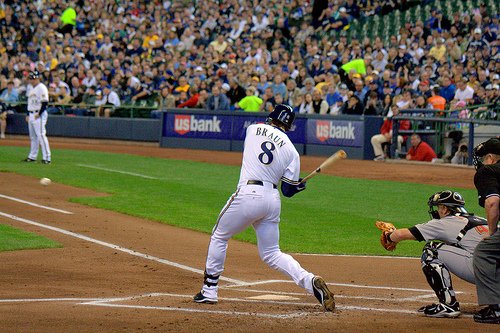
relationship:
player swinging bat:
[194, 103, 334, 311] [298, 151, 346, 187]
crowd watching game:
[0, 1, 499, 124] [0, 116, 497, 320]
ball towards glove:
[39, 175, 53, 189] [374, 221, 398, 251]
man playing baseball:
[194, 103, 334, 311] [0, 116, 497, 320]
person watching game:
[235, 87, 264, 111] [0, 116, 497, 320]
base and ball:
[248, 287, 302, 303] [39, 175, 53, 189]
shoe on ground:
[191, 290, 218, 303] [82, 287, 413, 332]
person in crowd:
[211, 34, 229, 51] [0, 1, 499, 124]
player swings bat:
[194, 103, 334, 311] [298, 151, 346, 187]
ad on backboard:
[164, 115, 231, 138] [161, 109, 233, 150]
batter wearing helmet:
[194, 103, 334, 311] [267, 105, 293, 129]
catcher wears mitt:
[374, 192, 500, 315] [374, 221, 398, 251]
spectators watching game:
[0, 1, 499, 124] [0, 116, 497, 320]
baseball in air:
[39, 175, 53, 189] [30, 161, 68, 205]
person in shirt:
[235, 87, 264, 111] [242, 98, 260, 110]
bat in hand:
[298, 151, 346, 187] [293, 180, 304, 189]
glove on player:
[374, 221, 398, 251] [374, 192, 500, 315]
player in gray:
[374, 192, 500, 315] [418, 217, 495, 282]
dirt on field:
[2, 173, 499, 331] [1, 135, 499, 326]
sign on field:
[164, 115, 231, 138] [1, 135, 499, 326]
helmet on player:
[267, 105, 293, 129] [194, 103, 334, 311]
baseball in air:
[41, 179, 52, 189] [30, 161, 68, 205]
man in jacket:
[407, 135, 437, 163] [407, 142, 434, 158]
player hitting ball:
[194, 103, 334, 311] [39, 175, 53, 189]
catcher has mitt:
[374, 192, 500, 315] [374, 221, 398, 251]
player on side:
[25, 71, 52, 164] [2, 1, 66, 322]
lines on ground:
[81, 289, 330, 321] [82, 287, 413, 332]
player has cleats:
[194, 103, 334, 311] [310, 277, 335, 311]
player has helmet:
[25, 71, 52, 164] [267, 105, 293, 129]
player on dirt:
[194, 103, 334, 311] [2, 173, 499, 331]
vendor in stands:
[338, 56, 372, 87] [0, 1, 499, 124]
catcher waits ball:
[374, 188, 495, 316] [39, 175, 53, 189]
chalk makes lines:
[1, 276, 462, 333] [81, 289, 330, 321]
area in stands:
[316, 3, 499, 60] [0, 1, 499, 124]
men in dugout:
[383, 105, 443, 160] [380, 100, 497, 177]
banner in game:
[164, 115, 231, 138] [0, 116, 497, 320]